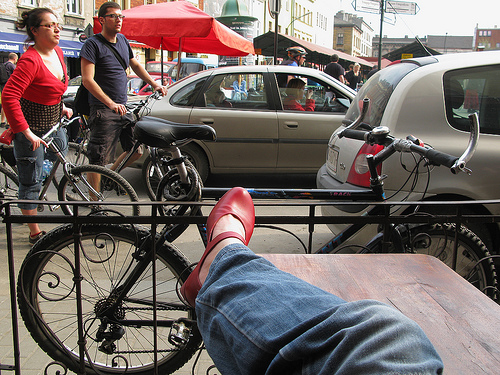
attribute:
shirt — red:
[277, 95, 322, 110]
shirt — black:
[319, 61, 344, 78]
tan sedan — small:
[155, 58, 342, 158]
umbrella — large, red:
[92, 2, 255, 59]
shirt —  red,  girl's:
[1, 36, 114, 141]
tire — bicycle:
[11, 218, 202, 368]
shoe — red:
[172, 183, 262, 315]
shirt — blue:
[77, 29, 137, 106]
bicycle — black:
[13, 92, 499, 373]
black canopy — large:
[252, 28, 376, 74]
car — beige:
[124, 64, 356, 184]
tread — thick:
[462, 224, 492, 259]